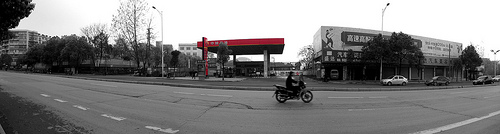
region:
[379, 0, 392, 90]
tall streetlamp post visible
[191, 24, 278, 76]
red canopy on building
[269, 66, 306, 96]
person is riding by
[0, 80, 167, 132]
white hash marks on road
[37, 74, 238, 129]
road is light grey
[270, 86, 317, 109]
cycle has black wheels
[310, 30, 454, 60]
wall of building is white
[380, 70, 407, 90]
car under building is white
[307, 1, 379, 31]
sky is light grey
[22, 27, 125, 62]
dark trees left of red building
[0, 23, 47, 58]
building left of trees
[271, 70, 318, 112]
person driving a motorcycle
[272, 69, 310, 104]
a man on a motorcycle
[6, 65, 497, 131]
a paved city street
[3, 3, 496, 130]
a fisheye lens photo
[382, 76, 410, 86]
a parked silver car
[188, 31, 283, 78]
a red gas station canopy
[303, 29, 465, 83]
a long white building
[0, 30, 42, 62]
a building in distance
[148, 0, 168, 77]
an overhead street light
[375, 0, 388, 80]
an overhead street light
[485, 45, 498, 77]
an overhead street light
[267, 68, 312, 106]
A person on a motorcycle.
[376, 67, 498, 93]
Cars on the road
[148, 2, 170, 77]
A street light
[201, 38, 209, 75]
A sign for the gas station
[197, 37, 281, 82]
A red gas station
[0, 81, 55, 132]
Shadows on the ground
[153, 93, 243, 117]
Cracks in the roadway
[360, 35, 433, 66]
Trees in front of the building.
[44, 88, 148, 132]
Marking in the road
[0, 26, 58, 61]
Building behind the trees.